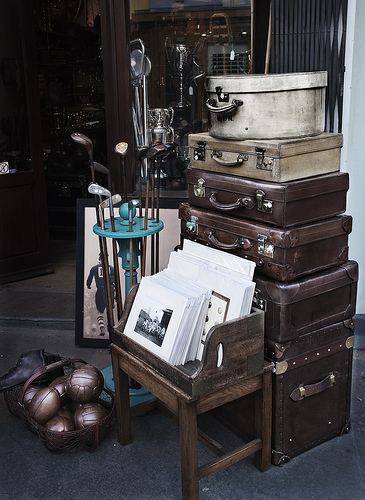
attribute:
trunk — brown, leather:
[240, 137, 333, 177]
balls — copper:
[27, 373, 93, 420]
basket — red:
[45, 434, 103, 454]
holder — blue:
[78, 195, 149, 285]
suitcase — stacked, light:
[264, 190, 345, 220]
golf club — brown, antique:
[54, 124, 116, 225]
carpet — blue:
[94, 462, 156, 478]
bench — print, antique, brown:
[177, 394, 224, 410]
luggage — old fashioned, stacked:
[203, 79, 319, 136]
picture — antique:
[64, 208, 110, 339]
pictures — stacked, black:
[123, 288, 195, 346]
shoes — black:
[3, 345, 41, 383]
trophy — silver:
[143, 96, 177, 163]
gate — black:
[0, 78, 101, 131]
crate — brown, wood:
[144, 351, 226, 396]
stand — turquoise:
[75, 353, 144, 406]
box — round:
[220, 108, 317, 142]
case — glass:
[161, 168, 180, 192]